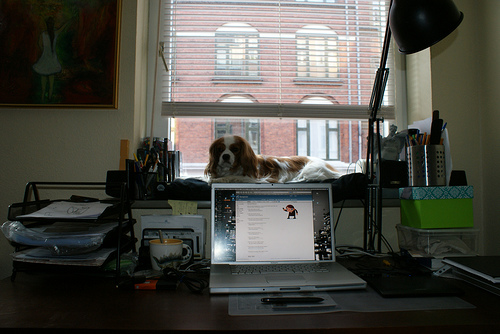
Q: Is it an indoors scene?
A: Yes, it is indoors.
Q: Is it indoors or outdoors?
A: It is indoors.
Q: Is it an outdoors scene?
A: No, it is indoors.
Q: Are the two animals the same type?
A: No, they are dogs and seals.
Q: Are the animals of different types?
A: Yes, they are dogs and seals.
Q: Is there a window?
A: Yes, there is a window.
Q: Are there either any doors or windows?
A: Yes, there is a window.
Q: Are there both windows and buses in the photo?
A: No, there is a window but no buses.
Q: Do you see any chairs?
A: No, there are no chairs.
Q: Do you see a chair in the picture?
A: No, there are no chairs.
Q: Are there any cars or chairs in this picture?
A: No, there are no chairs or cars.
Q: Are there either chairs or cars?
A: No, there are no chairs or cars.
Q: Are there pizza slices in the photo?
A: No, there are no pizza slices.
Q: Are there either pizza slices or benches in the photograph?
A: No, there are no pizza slices or benches.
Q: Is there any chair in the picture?
A: No, there are no chairs.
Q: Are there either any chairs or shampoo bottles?
A: No, there are no chairs or shampoo bottles.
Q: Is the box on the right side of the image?
A: Yes, the box is on the right of the image.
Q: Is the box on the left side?
A: No, the box is on the right of the image.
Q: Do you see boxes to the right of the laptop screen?
A: Yes, there is a box to the right of the screen.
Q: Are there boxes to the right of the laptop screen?
A: Yes, there is a box to the right of the screen.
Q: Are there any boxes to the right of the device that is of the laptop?
A: Yes, there is a box to the right of the screen.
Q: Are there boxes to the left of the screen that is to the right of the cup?
A: No, the box is to the right of the screen.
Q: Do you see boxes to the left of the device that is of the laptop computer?
A: No, the box is to the right of the screen.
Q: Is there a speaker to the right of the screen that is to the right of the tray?
A: No, there is a box to the right of the screen.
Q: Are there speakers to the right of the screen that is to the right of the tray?
A: No, there is a box to the right of the screen.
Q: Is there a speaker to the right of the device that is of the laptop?
A: No, there is a box to the right of the screen.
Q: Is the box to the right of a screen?
A: Yes, the box is to the right of a screen.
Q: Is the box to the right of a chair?
A: No, the box is to the right of a screen.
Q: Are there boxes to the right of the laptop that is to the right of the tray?
A: Yes, there is a box to the right of the laptop.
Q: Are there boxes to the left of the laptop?
A: No, the box is to the right of the laptop.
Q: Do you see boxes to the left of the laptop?
A: No, the box is to the right of the laptop.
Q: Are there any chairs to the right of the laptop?
A: No, there is a box to the right of the laptop.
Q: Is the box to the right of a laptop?
A: Yes, the box is to the right of a laptop.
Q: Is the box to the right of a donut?
A: No, the box is to the right of a laptop.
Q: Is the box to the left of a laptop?
A: No, the box is to the right of a laptop.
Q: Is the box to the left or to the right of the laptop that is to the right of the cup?
A: The box is to the right of the laptop.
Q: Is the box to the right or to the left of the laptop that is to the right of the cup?
A: The box is to the right of the laptop.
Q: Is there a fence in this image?
A: No, there are no fences.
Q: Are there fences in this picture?
A: No, there are no fences.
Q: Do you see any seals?
A: Yes, there is a seal.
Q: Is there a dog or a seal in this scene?
A: Yes, there is a seal.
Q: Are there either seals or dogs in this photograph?
A: Yes, there is a seal.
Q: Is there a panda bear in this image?
A: No, there are no panda bears.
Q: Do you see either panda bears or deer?
A: No, there are no panda bears or deer.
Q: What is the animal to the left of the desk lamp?
A: The animal is a seal.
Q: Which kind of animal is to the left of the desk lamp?
A: The animal is a seal.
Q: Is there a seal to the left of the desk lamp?
A: Yes, there is a seal to the left of the desk lamp.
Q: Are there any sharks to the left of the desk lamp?
A: No, there is a seal to the left of the desk lamp.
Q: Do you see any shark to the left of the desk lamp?
A: No, there is a seal to the left of the desk lamp.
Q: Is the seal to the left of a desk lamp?
A: Yes, the seal is to the left of a desk lamp.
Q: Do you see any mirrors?
A: No, there are no mirrors.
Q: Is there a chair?
A: No, there are no chairs.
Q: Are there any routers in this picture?
A: No, there are no routers.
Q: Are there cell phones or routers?
A: No, there are no routers or cell phones.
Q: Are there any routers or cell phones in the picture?
A: No, there are no routers or cell phones.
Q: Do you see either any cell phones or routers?
A: No, there are no routers or cell phones.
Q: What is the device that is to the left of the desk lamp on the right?
A: The device is a screen.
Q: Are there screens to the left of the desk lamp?
A: Yes, there is a screen to the left of the desk lamp.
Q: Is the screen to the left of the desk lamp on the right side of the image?
A: Yes, the screen is to the left of the desk lamp.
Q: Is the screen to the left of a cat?
A: No, the screen is to the left of the desk lamp.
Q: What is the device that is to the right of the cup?
A: The device is a screen.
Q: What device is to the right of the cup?
A: The device is a screen.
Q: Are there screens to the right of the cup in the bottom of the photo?
A: Yes, there is a screen to the right of the cup.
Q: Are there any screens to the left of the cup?
A: No, the screen is to the right of the cup.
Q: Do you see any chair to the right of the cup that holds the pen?
A: No, there is a screen to the right of the cup.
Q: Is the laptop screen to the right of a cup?
A: Yes, the screen is to the right of a cup.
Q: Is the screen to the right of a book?
A: No, the screen is to the right of a cup.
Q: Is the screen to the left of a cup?
A: No, the screen is to the right of a cup.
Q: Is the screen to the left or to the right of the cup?
A: The screen is to the right of the cup.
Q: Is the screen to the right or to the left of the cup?
A: The screen is to the right of the cup.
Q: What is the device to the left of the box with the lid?
A: The device is a screen.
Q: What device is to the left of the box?
A: The device is a screen.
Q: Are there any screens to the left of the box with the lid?
A: Yes, there is a screen to the left of the box.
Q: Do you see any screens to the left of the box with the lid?
A: Yes, there is a screen to the left of the box.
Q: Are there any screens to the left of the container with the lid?
A: Yes, there is a screen to the left of the box.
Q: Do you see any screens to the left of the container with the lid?
A: Yes, there is a screen to the left of the box.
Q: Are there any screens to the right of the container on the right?
A: No, the screen is to the left of the box.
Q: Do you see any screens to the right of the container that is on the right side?
A: No, the screen is to the left of the box.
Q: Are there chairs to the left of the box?
A: No, there is a screen to the left of the box.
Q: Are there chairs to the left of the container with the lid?
A: No, there is a screen to the left of the box.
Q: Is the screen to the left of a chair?
A: No, the screen is to the left of the box.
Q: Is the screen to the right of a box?
A: No, the screen is to the left of a box.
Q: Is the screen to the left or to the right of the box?
A: The screen is to the left of the box.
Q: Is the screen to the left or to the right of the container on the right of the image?
A: The screen is to the left of the box.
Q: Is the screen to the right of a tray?
A: Yes, the screen is to the right of a tray.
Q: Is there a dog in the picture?
A: Yes, there is a dog.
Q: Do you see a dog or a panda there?
A: Yes, there is a dog.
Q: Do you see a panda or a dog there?
A: Yes, there is a dog.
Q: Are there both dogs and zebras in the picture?
A: No, there is a dog but no zebras.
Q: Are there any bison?
A: No, there are no bison.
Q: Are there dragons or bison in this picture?
A: No, there are no bison or dragons.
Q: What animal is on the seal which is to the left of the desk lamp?
A: The animal is a dog.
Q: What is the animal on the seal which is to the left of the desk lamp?
A: The animal is a dog.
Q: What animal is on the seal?
A: The animal is a dog.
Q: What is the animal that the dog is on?
A: The animal is a seal.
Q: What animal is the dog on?
A: The dog is on the seal.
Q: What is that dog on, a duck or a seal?
A: The dog is on a seal.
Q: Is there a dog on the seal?
A: Yes, there is a dog on the seal.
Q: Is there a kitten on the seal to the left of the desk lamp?
A: No, there is a dog on the seal.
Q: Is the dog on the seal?
A: Yes, the dog is on the seal.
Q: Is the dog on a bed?
A: No, the dog is on the seal.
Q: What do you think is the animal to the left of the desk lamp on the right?
A: The animal is a dog.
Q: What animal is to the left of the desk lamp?
A: The animal is a dog.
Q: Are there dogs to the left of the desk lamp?
A: Yes, there is a dog to the left of the desk lamp.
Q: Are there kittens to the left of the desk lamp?
A: No, there is a dog to the left of the desk lamp.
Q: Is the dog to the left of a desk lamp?
A: Yes, the dog is to the left of a desk lamp.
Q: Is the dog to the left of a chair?
A: No, the dog is to the left of a desk lamp.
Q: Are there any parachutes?
A: No, there are no parachutes.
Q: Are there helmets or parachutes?
A: No, there are no parachutes or helmets.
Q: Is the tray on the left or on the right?
A: The tray is on the left of the image.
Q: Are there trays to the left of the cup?
A: Yes, there is a tray to the left of the cup.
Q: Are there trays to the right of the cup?
A: No, the tray is to the left of the cup.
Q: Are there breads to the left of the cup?
A: No, there is a tray to the left of the cup.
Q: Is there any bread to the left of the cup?
A: No, there is a tray to the left of the cup.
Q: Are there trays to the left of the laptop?
A: Yes, there is a tray to the left of the laptop.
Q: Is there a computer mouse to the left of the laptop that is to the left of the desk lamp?
A: No, there is a tray to the left of the laptop computer.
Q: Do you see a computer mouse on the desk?
A: No, there is a tray on the desk.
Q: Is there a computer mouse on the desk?
A: No, there is a tray on the desk.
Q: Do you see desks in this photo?
A: Yes, there is a desk.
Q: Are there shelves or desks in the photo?
A: Yes, there is a desk.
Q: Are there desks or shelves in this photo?
A: Yes, there is a desk.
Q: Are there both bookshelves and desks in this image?
A: No, there is a desk but no bookshelves.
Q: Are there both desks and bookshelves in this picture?
A: No, there is a desk but no bookshelves.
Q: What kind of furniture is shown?
A: The furniture is a desk.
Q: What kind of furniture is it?
A: The piece of furniture is a desk.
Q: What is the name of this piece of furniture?
A: This is a desk.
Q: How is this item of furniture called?
A: This is a desk.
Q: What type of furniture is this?
A: This is a desk.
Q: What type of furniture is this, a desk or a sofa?
A: This is a desk.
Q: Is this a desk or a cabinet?
A: This is a desk.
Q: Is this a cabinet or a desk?
A: This is a desk.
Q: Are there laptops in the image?
A: Yes, there is a laptop.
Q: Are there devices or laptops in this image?
A: Yes, there is a laptop.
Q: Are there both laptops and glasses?
A: No, there is a laptop but no glasses.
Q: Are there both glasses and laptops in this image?
A: No, there is a laptop but no glasses.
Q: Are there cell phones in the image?
A: No, there are no cell phones.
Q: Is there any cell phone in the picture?
A: No, there are no cell phones.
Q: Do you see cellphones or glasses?
A: No, there are no cellphones or glasses.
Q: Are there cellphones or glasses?
A: No, there are no cellphones or glasses.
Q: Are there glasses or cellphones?
A: No, there are no cellphones or glasses.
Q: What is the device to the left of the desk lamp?
A: The device is a laptop.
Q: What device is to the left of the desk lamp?
A: The device is a laptop.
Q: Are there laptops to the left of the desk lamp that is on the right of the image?
A: Yes, there is a laptop to the left of the desk lamp.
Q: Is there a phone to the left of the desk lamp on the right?
A: No, there is a laptop to the left of the desk lamp.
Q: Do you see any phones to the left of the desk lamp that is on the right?
A: No, there is a laptop to the left of the desk lamp.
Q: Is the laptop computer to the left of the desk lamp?
A: Yes, the laptop computer is to the left of the desk lamp.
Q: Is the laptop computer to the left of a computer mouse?
A: No, the laptop computer is to the left of the desk lamp.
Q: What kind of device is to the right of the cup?
A: The device is a laptop.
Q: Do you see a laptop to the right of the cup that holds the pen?
A: Yes, there is a laptop to the right of the cup.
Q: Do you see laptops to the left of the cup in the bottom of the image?
A: No, the laptop is to the right of the cup.